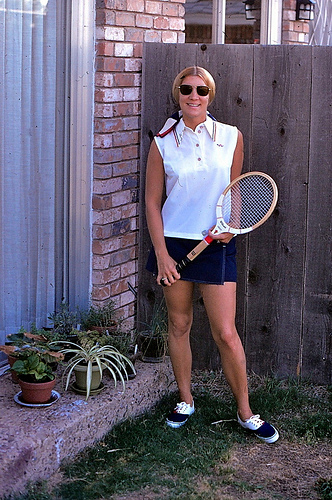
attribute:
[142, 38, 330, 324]
fence — brown, wooden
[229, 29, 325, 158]
fence — weathered , gray, wooden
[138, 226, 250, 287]
skirt — short, blue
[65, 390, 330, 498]
grass — dark, green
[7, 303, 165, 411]
plants — potted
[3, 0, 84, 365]
glass door — sliding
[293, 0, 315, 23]
light — black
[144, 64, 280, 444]
person — polo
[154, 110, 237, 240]
shirt — white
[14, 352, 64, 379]
plant — potted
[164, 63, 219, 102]
hair — blonde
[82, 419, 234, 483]
grass — patchy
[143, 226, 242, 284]
skirt — blue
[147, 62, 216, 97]
hair — short, blonde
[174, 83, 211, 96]
sunglasses — dark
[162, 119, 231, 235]
shirt — white, sleeveless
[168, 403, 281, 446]
sneaker — white 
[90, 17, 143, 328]
wall — red, brick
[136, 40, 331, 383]
fence — wood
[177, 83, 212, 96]
sunglasses — black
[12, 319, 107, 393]
plants — potted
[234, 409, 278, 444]
shoe — blue, white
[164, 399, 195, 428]
shoe — blue, white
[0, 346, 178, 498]
stoop — concrete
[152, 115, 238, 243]
top — white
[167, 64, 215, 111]
hair — blonde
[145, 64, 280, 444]
player — female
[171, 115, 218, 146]
collar — pointy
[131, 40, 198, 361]
plank — wide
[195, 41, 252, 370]
plank — wide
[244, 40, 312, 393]
plank — wide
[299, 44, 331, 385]
plank — wide